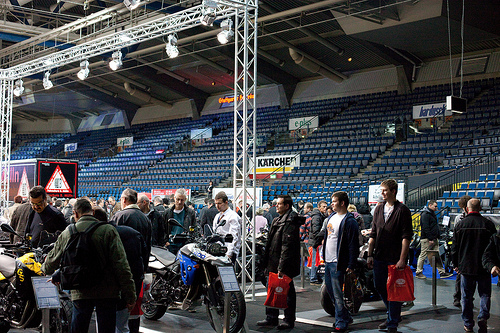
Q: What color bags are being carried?
A: Orange.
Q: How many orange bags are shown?
A: 2.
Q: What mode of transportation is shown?
A: Motorcycle.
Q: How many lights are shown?
A: 6.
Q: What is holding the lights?
A: Metal railing.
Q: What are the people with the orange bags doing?
A: Standing.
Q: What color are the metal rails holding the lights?
A: Silver.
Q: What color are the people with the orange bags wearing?
A: Black.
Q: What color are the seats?
A: Blue.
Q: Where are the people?
A: Gym floor.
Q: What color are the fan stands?
A: Blue and gray.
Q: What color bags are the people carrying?
A: Orange.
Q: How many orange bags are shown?
A: 2.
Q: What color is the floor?
A: Gray.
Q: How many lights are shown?
A: 6.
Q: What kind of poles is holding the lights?
A: Metal.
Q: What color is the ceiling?
A: Gray.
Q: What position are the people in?
A: Standing.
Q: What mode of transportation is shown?
A: Motorcycle.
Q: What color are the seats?
A: Blue.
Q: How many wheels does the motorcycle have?
A: Two.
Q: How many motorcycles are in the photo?
A: Two.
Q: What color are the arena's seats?
A: Blue.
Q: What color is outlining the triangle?
A: Red.